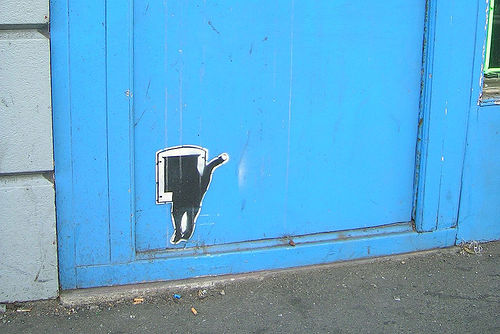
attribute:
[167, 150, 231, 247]
cat — black, white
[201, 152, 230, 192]
tail — black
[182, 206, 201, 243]
leg — back leg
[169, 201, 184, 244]
leg — back leg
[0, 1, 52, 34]
brick — large, grey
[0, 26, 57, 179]
brick — large, grey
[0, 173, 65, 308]
brick — large, grey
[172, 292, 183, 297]
gum — used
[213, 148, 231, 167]
tail — white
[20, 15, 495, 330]
building — green 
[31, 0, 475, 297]
wall — blue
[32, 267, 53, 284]
marks — scuff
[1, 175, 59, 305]
brick — gray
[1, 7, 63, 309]
wall — gray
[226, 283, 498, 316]
street — black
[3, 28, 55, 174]
block — concrete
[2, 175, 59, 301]
block — concrete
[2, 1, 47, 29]
block — concrete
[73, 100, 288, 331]
door — Blue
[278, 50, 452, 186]
door — bright blue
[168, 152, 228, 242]
cat — painted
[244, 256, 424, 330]
ground — dark, cement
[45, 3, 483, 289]
door — wooden, blue, old, painted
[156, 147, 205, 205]
opening — small